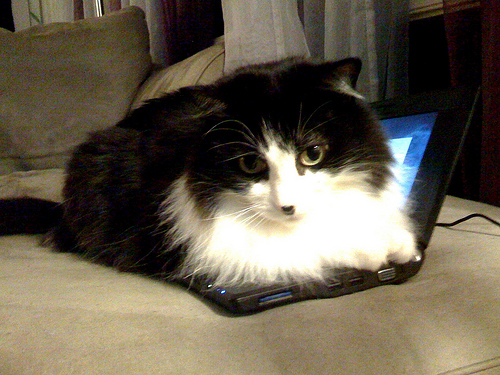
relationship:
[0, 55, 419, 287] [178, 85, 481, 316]
cat sitting on laptop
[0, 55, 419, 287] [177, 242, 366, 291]
cat smothering keys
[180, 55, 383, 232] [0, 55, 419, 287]
head of cat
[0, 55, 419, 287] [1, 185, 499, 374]
cat sitting on chair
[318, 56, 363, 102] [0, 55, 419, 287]
ear of cat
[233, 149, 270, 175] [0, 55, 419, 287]
eye of cat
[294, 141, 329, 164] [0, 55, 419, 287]
eye of cat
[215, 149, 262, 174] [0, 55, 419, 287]
whisker of cat